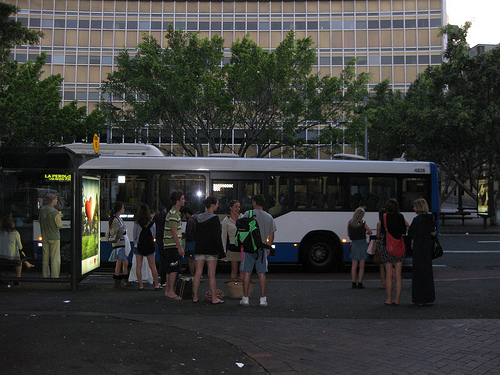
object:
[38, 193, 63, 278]
man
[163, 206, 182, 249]
shirt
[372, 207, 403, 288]
women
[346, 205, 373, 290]
women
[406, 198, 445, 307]
people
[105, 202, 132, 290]
people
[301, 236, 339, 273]
back tire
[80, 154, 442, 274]
bus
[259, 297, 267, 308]
sneaker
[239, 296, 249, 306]
sneaker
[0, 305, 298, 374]
pavement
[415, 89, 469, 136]
leaves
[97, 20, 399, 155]
tree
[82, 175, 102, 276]
advertisement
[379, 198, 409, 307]
woman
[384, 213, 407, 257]
red purse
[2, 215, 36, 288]
woman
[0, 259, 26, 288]
bench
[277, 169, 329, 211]
window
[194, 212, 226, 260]
hoodie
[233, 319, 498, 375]
pattern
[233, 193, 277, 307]
man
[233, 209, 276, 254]
backpack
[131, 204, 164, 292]
people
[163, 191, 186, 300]
man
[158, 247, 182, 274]
black shorts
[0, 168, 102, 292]
bus stop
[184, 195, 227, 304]
woman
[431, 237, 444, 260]
purse